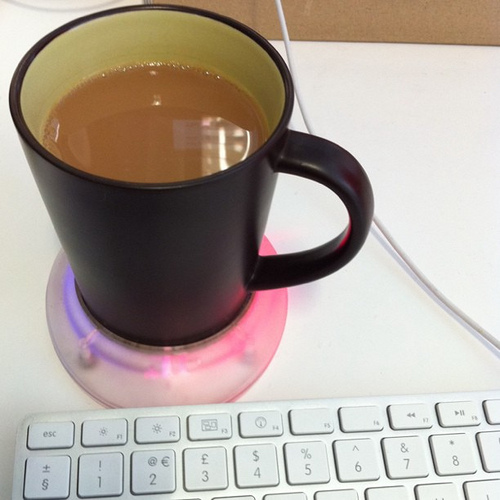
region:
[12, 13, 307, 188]
cup filled half way with coffee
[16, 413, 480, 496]
white keyboard with white keys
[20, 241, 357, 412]
cup rest that lights up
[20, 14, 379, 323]
black coffee cup with handle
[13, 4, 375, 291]
one coffee mug with handle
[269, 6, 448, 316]
white electrical cord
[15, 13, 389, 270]
black coffee cup filled with coffee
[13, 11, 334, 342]
black cup in coffee holder that lights up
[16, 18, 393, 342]
one mug with one handle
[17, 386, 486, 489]
European keyboard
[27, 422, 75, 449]
An escape key on a macintosh.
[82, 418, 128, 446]
An F1 key on a macintosh.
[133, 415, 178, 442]
An F2 key on a macintosh.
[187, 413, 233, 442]
An F3 key on a macintosh.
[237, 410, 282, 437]
An F4 key on a macintosh.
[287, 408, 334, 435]
An F5 key on a macintosh.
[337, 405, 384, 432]
An F6 key on a macintosh.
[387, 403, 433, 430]
An F7 key on a macintosh.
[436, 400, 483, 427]
An F8 key on a macintosh.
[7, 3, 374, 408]
A coffee mug on a mug warmer.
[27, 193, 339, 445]
led illuminated cup holder is clear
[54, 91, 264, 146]
Liquid Coffee inside a cup.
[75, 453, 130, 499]
The #1 key on an Apple Key.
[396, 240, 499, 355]
A white Apple cable wire.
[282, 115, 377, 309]
The Curved Handle of a Mug.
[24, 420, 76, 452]
The Escape Key of an Apple Key.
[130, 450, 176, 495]
The #2 Key of an Apple Keyboard.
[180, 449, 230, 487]
The #3 Key of the Apple Keyboard.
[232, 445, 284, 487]
The #4 Key of the Apple Keyboard.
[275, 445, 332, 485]
The #5 Key of an Apple Keyboard.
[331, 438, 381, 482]
The #6 Key of the Apple Keyboard.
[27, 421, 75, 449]
An escape key on a Macintosh keyboard.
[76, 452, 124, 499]
A 1 key on a macintosh keyboard.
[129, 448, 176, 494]
A 2 key on a macintosh keyboard.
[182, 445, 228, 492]
A 3 key on a macintosh keyboard.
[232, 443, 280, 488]
A 4 key on a macintosh keyboard.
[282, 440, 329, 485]
A 5 key on a macintosh keyboard.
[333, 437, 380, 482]
A 6 key on a macintosh keyboard.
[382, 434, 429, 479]
A 7 key on a macintosh keyboard.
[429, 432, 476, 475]
An 8 key on a macintosh keyboard.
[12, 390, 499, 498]
A macintosh keyboard.